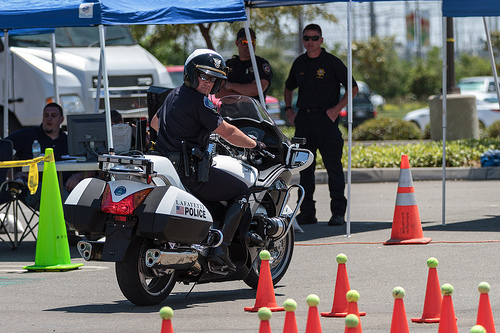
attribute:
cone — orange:
[242, 250, 282, 311]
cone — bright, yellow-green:
[15, 147, 103, 281]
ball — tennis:
[158, 306, 175, 320]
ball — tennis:
[258, 247, 270, 261]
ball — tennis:
[256, 305, 273, 320]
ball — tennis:
[282, 297, 297, 312]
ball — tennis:
[306, 292, 320, 306]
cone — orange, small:
[322, 264, 364, 316]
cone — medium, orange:
[381, 151, 431, 244]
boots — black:
[208, 179, 239, 265]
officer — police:
[158, 49, 268, 293]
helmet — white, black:
[161, 43, 245, 88]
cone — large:
[378, 147, 435, 254]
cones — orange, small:
[145, 251, 500, 331]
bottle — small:
[27, 137, 42, 157]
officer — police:
[149, 44, 271, 274]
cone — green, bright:
[26, 149, 80, 271]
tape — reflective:
[392, 167, 417, 187]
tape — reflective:
[392, 190, 422, 208]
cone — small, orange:
[279, 243, 416, 315]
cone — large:
[23, 141, 81, 273]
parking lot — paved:
[4, 164, 498, 331]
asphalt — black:
[332, 235, 435, 271]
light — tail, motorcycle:
[107, 193, 131, 212]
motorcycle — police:
[69, 92, 302, 302]